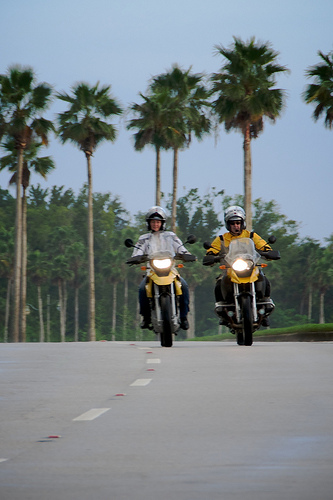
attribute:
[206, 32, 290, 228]
tree — palm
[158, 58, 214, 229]
tree — palm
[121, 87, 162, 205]
tree — palm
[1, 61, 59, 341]
tree — palm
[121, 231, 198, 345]
motorcycle — bright yellow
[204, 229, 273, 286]
jacket — yellow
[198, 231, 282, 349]
motorcycle — bright yellow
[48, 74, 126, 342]
tree — palm, tall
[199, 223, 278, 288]
coat — yellow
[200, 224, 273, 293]
coat — yellow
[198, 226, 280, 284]
coat — yellow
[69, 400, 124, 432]
line — white 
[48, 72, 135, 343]
tree — tall 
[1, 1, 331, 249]
sky — blue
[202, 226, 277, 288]
jacket — yellow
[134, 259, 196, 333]
pants — dark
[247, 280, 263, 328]
support — metal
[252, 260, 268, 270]
light — orange